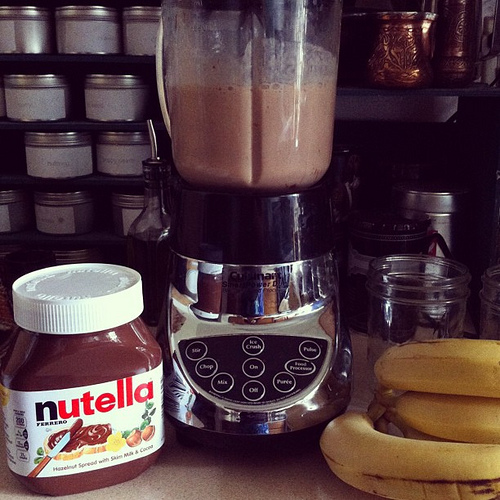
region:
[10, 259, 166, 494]
a jar of nutella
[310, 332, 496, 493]
a bunch of bananas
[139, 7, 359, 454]
a blender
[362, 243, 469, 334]
an empty jar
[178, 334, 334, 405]
The buttons on the blender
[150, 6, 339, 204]
The blender pitcher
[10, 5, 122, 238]
several small silver containers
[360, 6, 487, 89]
a copper container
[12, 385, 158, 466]
the label on the jar of nutella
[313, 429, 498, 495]
The banana in the front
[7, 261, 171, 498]
new jar of nutella spread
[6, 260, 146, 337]
white jar lid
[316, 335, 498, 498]
a bunch of yellow ripe bananas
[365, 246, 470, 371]
empty glass clear container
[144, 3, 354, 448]
a cuisinart blender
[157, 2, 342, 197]
blender's container filled with a mixture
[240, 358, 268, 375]
blender's power button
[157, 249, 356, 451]
silver base of a blender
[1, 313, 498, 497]
counter in a kitchen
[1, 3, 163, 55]
jars on a shelf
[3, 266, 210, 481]
Nutella on a counter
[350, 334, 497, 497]
Bananas on a counter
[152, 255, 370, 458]
Silver mixer on a counter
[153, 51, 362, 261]
Brown liquid in a mixer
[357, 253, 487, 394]
Glass jar on a counter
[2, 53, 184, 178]
Shelves with jars in them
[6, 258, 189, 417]
White lid on a jar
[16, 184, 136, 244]
Silver lid on a jar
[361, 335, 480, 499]
four bananas on a counter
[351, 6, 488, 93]
Bronze jar on a shelf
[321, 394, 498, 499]
banana to the right of blender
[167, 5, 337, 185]
blender jar is clear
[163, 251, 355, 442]
base of the blender is chrome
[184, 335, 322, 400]
buttons on the blender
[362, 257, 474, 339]
empty jar behind bananas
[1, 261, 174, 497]
jar of nutella to the left of the blender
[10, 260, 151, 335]
jar lid is white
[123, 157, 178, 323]
bottle to the right of blender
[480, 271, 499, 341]
part of another empty jar visible behind bananas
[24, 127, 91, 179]
canisters behind the blender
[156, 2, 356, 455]
the blender has many buttons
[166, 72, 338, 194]
the blender has a milkshake in it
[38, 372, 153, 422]
the jar says nutella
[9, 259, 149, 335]
the jar has a white top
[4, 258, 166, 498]
the jar is brown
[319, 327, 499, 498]
the bananas are yellow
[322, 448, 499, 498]
the bananas have brown spots on them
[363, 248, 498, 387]
the jars are made of glass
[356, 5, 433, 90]
a copper decorative jar sits on the shelf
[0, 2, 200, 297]
the shelf has ingredient containers on it